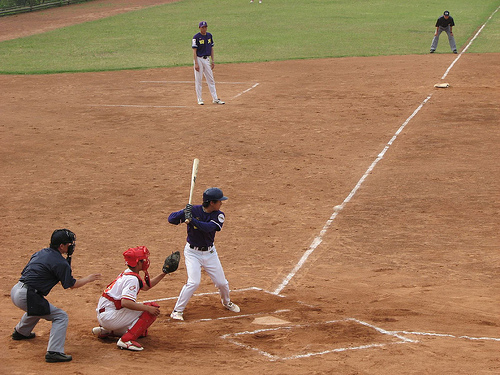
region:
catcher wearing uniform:
[89, 239, 186, 355]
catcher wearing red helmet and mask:
[113, 240, 156, 280]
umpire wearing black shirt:
[6, 224, 102, 286]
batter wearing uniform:
[156, 164, 253, 326]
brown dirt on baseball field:
[17, 86, 182, 204]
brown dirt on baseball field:
[276, 78, 368, 153]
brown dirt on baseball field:
[387, 167, 497, 315]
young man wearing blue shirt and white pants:
[161, 10, 256, 120]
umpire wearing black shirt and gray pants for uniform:
[414, 7, 475, 64]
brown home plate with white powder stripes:
[241, 263, 410, 364]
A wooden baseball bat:
[181, 153, 203, 229]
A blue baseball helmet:
[196, 182, 229, 214]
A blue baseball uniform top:
[164, 204, 231, 255]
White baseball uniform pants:
[171, 242, 243, 320]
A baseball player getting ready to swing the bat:
[163, 148, 250, 329]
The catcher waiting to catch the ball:
[84, 244, 184, 371]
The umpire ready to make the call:
[9, 222, 104, 369]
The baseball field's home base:
[241, 312, 293, 338]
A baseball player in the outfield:
[179, 1, 222, 115]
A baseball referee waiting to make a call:
[424, 5, 464, 60]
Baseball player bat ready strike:
[159, 139, 255, 327]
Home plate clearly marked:
[239, 301, 309, 340]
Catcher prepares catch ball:
[99, 242, 177, 361]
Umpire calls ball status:
[15, 219, 84, 358]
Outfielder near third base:
[413, 6, 475, 64]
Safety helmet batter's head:
[197, 186, 237, 230]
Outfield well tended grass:
[84, 6, 416, 58]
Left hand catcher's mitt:
[144, 241, 182, 287]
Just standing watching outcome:
[181, 18, 241, 111]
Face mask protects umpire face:
[35, 226, 87, 271]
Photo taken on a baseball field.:
[1, 12, 492, 363]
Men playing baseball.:
[1, 1, 489, 368]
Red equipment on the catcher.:
[84, 221, 177, 357]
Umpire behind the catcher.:
[0, 198, 104, 365]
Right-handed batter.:
[151, 143, 256, 320]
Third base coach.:
[180, 8, 240, 115]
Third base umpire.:
[408, 3, 468, 53]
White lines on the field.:
[192, 10, 493, 373]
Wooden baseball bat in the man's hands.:
[178, 145, 210, 231]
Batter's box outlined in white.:
[156, 270, 432, 358]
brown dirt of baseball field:
[17, 76, 160, 196]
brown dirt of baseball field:
[279, 74, 381, 138]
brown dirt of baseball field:
[435, 110, 486, 297]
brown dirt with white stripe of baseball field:
[228, 120, 464, 270]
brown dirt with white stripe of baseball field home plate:
[146, 286, 411, 366]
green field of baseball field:
[256, 5, 422, 39]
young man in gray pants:
[147, 6, 254, 136]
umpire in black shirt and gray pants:
[8, 212, 107, 361]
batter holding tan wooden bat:
[146, 137, 205, 212]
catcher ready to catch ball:
[90, 200, 205, 368]